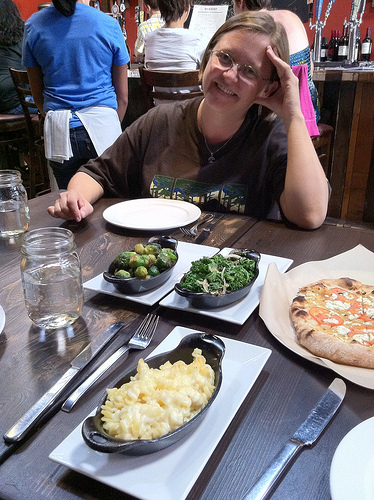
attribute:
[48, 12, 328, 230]
lady — smiling, dining, sitting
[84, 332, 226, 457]
pan — black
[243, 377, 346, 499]
knife — silver, metal, steel, shiny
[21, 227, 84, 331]
glass — half empty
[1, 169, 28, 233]
glass — half full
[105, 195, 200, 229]
plate — white, empty, ceramic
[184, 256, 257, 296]
vegetable — green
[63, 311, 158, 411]
fork — metal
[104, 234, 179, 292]
bowl — black, ceramic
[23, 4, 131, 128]
shirt — blue